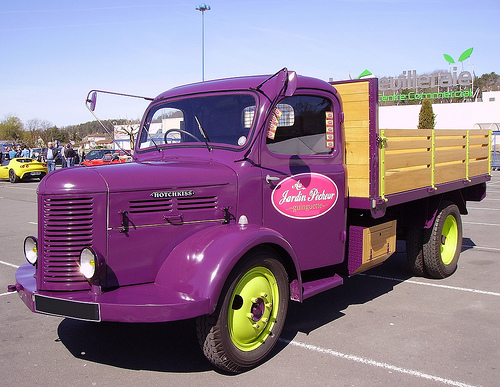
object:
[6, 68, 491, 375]
truck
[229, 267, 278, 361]
hubcap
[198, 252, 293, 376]
tire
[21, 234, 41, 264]
headlight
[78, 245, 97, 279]
headlight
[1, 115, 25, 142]
tree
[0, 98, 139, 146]
distance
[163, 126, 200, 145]
wheel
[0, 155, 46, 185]
car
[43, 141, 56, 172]
man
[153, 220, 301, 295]
fender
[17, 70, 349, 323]
paint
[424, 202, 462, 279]
wheel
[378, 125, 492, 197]
bed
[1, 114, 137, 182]
background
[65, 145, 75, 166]
people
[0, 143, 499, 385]
lot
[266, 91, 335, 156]
window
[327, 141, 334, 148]
sticker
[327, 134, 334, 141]
sticker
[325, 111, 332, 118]
sticker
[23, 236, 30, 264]
rim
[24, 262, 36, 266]
rim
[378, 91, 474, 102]
sign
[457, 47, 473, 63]
highlight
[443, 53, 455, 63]
highlight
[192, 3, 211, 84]
streetlight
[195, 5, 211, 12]
lamp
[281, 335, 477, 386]
line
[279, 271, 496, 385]
space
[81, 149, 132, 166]
car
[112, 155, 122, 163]
decor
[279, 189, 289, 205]
letter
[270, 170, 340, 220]
logo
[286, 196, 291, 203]
letter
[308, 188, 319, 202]
letter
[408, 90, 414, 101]
letter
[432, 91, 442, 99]
letter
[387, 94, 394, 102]
letter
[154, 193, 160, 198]
letter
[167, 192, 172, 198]
letter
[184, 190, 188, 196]
letter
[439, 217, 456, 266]
hubcap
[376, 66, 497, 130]
background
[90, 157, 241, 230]
door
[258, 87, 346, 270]
door